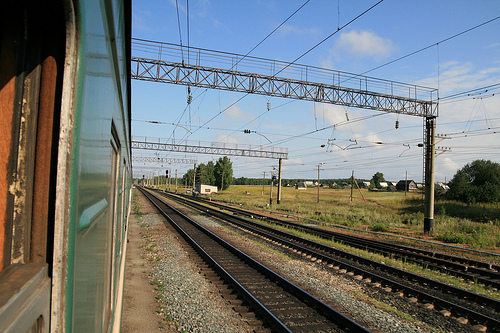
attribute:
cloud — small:
[328, 29, 400, 65]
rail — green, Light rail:
[68, 19, 137, 322]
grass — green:
[163, 181, 498, 301]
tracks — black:
[135, 186, 465, 331]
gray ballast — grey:
[158, 247, 353, 332]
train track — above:
[141, 182, 498, 331]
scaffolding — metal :
[138, 25, 443, 117]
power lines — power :
[135, 2, 498, 107]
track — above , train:
[130, 179, 498, 331]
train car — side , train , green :
[2, 0, 134, 330]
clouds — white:
[302, 90, 377, 141]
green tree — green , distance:
[445, 157, 499, 204]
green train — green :
[1, 0, 129, 330]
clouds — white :
[313, 99, 382, 149]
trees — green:
[182, 154, 234, 193]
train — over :
[4, 1, 134, 329]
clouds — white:
[126, 19, 496, 180]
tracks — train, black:
[139, 176, 497, 320]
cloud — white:
[434, 92, 499, 122]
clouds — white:
[342, 29, 392, 59]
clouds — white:
[404, 58, 499, 95]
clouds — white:
[313, 96, 355, 128]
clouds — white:
[226, 103, 252, 123]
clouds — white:
[331, 132, 383, 154]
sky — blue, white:
[132, 2, 499, 184]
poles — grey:
[421, 97, 441, 227]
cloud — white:
[328, 35, 394, 60]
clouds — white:
[338, 28, 388, 58]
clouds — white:
[208, 96, 267, 128]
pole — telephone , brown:
[314, 162, 321, 204]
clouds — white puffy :
[337, 30, 395, 58]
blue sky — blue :
[132, 0, 490, 98]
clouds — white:
[335, 31, 500, 185]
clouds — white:
[311, 100, 359, 132]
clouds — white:
[314, 100, 381, 157]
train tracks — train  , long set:
[132, 185, 498, 331]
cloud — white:
[329, 26, 367, 65]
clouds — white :
[299, 60, 382, 150]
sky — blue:
[128, 7, 476, 242]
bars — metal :
[131, 36, 443, 118]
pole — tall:
[312, 159, 320, 210]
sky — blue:
[289, 146, 331, 177]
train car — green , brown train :
[8, 22, 168, 244]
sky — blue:
[418, 22, 480, 39]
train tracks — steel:
[149, 194, 352, 330]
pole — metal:
[421, 113, 438, 233]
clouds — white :
[129, 7, 494, 192]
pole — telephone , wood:
[311, 160, 324, 210]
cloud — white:
[336, 24, 395, 61]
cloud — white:
[315, 102, 354, 132]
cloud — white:
[221, 99, 249, 123]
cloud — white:
[214, 133, 243, 150]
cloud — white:
[441, 154, 465, 172]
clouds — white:
[297, 9, 484, 156]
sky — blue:
[130, 0, 470, 157]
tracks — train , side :
[155, 173, 479, 323]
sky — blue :
[134, 6, 479, 178]